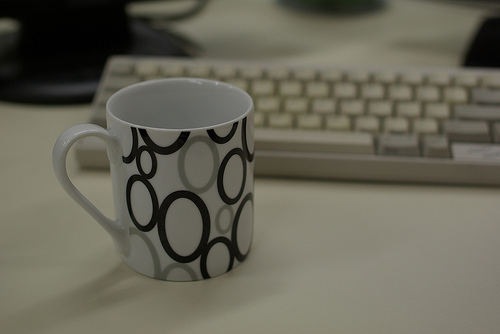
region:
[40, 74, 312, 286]
A ceramic tea cup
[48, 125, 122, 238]
Handle of the cup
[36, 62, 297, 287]
Black and white color of the ceramic cup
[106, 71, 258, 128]
Circle shape top of the ceramic cup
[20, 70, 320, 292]
A cup kept near the key board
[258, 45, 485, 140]
Key board near the cup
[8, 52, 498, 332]
Key board and cup kept above the table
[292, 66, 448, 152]
White color key board with numbers and letters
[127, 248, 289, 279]
Bottom of the cup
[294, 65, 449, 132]
Plastic keyboard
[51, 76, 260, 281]
black and white coffee mug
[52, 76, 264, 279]
white coffee mug with circle art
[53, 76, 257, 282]
empty coffee mug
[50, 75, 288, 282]
pop art coffee cup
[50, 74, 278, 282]
white mug on with grey and black circles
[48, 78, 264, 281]
modern art coffee cup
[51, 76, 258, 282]
white coffee mug with circle design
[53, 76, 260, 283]
empty mug no coffee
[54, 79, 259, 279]
empty coffee mug on white table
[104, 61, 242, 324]
white and black mug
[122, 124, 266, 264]
black and grey circles on mug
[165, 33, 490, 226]
white keyboard behind mug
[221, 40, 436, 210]
keyboard on white table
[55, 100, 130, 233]
mug has white handle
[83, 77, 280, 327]
mug on white table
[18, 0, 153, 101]
black monitor behind keyboard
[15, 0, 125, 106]
monitor on white table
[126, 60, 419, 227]
keyboard is legacy model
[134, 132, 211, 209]
grey circles on mug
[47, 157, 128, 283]
part of a handle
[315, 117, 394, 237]
part of a keyboard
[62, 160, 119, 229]
part of a handle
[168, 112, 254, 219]
edge of a cup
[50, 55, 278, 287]
a cup is on the table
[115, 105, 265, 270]
there are circles on the cup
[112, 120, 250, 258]
the circles are black and grey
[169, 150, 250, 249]
the circles are big and small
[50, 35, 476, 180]
there is a keyboard behind the cup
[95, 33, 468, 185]
the keyboard is white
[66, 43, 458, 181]
the keyboard is blurry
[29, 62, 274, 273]
the cup is empty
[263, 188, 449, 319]
the table is white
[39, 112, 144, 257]
the cup has a handle